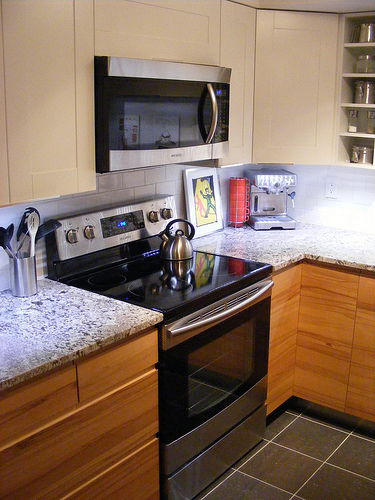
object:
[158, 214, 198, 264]
kettle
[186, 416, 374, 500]
linoleum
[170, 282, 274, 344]
handle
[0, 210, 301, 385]
countertop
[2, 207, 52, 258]
utensils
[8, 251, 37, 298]
pot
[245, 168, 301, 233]
machine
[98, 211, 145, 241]
display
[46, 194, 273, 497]
stove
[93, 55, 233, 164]
microwave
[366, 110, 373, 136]
shaker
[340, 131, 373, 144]
self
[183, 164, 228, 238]
picture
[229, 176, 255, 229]
cups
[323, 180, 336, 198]
outlet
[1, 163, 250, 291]
wall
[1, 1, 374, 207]
cabinets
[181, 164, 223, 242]
frame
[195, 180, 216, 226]
man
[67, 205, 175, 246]
knobs